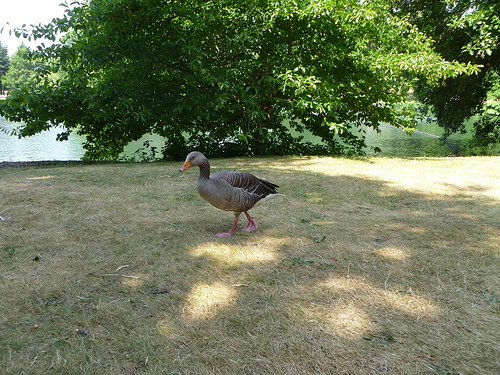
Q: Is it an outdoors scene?
A: Yes, it is outdoors.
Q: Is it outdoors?
A: Yes, it is outdoors.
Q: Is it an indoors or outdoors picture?
A: It is outdoors.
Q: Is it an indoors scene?
A: No, it is outdoors.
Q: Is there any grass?
A: Yes, there is grass.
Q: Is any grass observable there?
A: Yes, there is grass.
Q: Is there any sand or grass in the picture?
A: Yes, there is grass.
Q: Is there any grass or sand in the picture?
A: Yes, there is grass.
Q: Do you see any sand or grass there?
A: Yes, there is grass.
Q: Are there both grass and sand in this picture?
A: No, there is grass but no sand.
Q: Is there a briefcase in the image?
A: No, there are no briefcases.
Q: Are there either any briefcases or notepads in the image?
A: No, there are no briefcases or notepads.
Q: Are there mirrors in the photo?
A: No, there are no mirrors.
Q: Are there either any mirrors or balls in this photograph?
A: No, there are no mirrors or balls.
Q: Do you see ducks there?
A: Yes, there is a duck.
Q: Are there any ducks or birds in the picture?
A: Yes, there is a duck.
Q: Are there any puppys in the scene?
A: No, there are no puppys.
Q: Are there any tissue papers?
A: No, there are no tissue papers.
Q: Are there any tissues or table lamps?
A: No, there are no tissues or table lamps.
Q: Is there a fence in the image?
A: No, there are no fences.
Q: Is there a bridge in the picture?
A: No, there are no bridges.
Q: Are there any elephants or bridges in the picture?
A: No, there are no bridges or elephants.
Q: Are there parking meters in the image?
A: No, there are no parking meters.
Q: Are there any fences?
A: No, there are no fences.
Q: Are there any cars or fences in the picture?
A: No, there are no fences or cars.